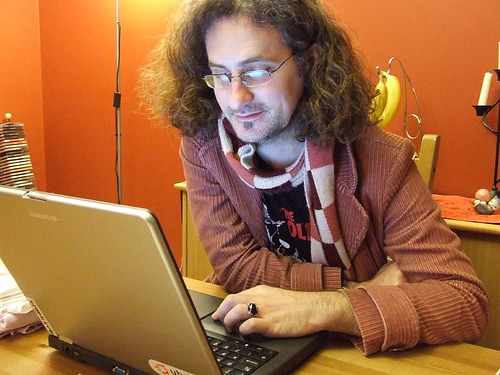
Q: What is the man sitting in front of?
A: Laptop.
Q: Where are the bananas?
A: Hanging from a stand on a side table behind the man.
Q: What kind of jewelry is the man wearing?
A: Ring on his left hand.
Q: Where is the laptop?
A: On a wood table.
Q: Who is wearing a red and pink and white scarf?
A: The man at the table.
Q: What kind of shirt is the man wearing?
A: Band t-shirt.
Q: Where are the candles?
A: On the table behind the man.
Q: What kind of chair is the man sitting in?
A: Wooden dining chair.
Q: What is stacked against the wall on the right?
A: CDs.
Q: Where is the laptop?
A: On desk.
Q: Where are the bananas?
A: Rack.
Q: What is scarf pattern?
A: Checkers.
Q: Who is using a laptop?
A: A man with cordoroy jacket.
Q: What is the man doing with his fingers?
A: Scrolling on the keypad.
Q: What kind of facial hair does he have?
A: Goatee.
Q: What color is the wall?
A: Tan.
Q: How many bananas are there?
A: Two.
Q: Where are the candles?
A: Behind the man on the desk.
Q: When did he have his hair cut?
A: A while ago.